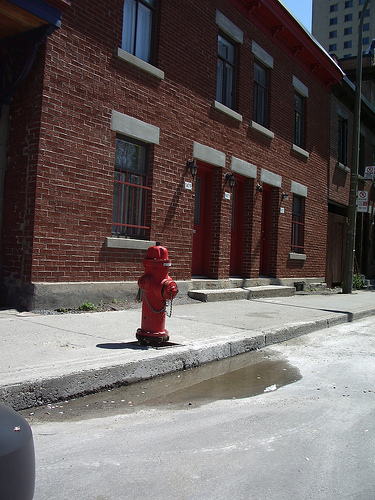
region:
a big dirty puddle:
[32, 344, 306, 413]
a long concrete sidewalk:
[2, 285, 373, 401]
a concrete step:
[191, 284, 246, 302]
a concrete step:
[248, 280, 294, 298]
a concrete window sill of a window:
[103, 235, 157, 251]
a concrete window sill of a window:
[288, 251, 307, 262]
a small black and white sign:
[355, 191, 368, 200]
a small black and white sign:
[362, 165, 373, 174]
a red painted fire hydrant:
[132, 239, 175, 343]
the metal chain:
[138, 278, 178, 314]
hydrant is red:
[127, 232, 182, 347]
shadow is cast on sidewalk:
[92, 337, 177, 355]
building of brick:
[4, 61, 354, 286]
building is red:
[3, 0, 359, 291]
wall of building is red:
[188, 155, 220, 278]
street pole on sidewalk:
[336, 1, 371, 301]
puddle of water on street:
[21, 343, 301, 414]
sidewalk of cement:
[175, 286, 371, 366]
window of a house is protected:
[96, 127, 160, 244]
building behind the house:
[306, 1, 373, 54]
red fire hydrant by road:
[121, 232, 217, 401]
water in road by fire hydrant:
[127, 254, 251, 397]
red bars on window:
[104, 109, 179, 248]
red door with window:
[192, 146, 219, 270]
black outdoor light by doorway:
[177, 146, 220, 185]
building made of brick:
[50, 91, 130, 277]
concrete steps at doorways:
[184, 228, 261, 319]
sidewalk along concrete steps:
[190, 280, 348, 316]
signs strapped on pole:
[344, 145, 373, 224]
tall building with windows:
[303, 4, 361, 68]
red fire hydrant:
[129, 238, 181, 352]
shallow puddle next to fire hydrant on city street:
[19, 334, 304, 426]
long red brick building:
[1, 0, 372, 317]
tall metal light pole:
[339, 0, 373, 296]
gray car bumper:
[0, 387, 39, 499]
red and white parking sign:
[356, 186, 369, 215]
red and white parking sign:
[362, 161, 373, 181]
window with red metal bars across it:
[100, 109, 161, 257]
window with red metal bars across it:
[289, 178, 309, 263]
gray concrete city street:
[0, 313, 373, 498]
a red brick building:
[0, 0, 354, 275]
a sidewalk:
[2, 291, 367, 359]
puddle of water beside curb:
[29, 341, 306, 412]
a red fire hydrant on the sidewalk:
[115, 237, 187, 350]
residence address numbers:
[177, 180, 285, 216]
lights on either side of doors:
[179, 156, 290, 280]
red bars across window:
[111, 131, 157, 235]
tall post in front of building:
[320, 0, 370, 294]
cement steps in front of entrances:
[185, 192, 295, 305]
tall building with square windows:
[313, 1, 368, 71]